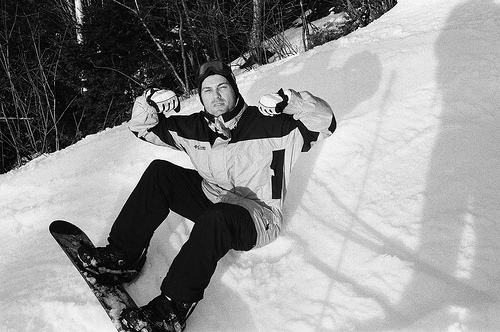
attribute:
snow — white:
[3, 2, 495, 326]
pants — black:
[77, 149, 274, 328]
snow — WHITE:
[373, 134, 499, 241]